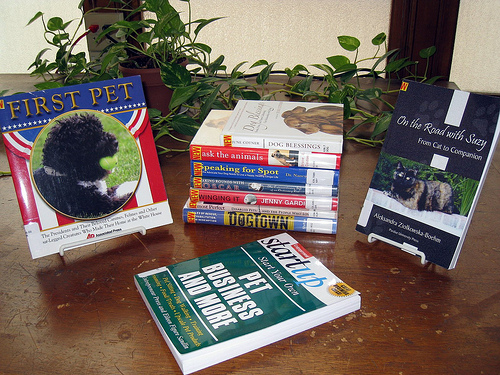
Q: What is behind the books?
A: A plant.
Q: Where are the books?
A: On the table.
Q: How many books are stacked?
A: Seven.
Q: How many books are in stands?
A: Two.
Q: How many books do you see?
A: Ten.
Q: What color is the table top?
A: Brown.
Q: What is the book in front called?
A: Pet Business and More.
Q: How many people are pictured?
A: Zero.